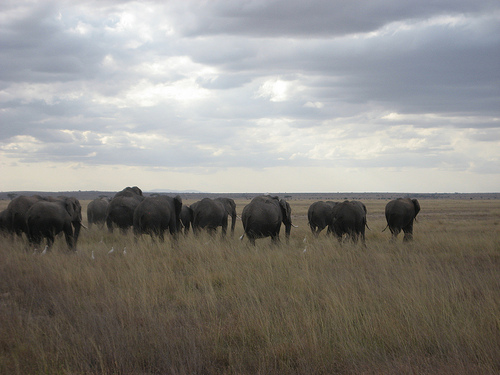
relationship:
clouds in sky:
[83, 47, 220, 136] [46, 8, 493, 144]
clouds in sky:
[316, 84, 389, 128] [93, 17, 444, 177]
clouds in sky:
[370, 81, 460, 141] [57, 8, 485, 178]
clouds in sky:
[95, 70, 149, 114] [74, 25, 483, 164]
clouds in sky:
[139, 49, 203, 92] [155, 51, 479, 190]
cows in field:
[16, 190, 425, 245] [0, 182, 483, 334]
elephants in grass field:
[11, 189, 431, 270] [31, 210, 485, 362]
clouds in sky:
[22, 28, 97, 125] [11, 32, 111, 89]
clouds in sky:
[330, 52, 416, 114] [38, 32, 468, 177]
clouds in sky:
[386, 13, 476, 78] [2, 2, 497, 191]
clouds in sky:
[3, 0, 496, 172] [2, 2, 497, 191]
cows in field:
[2, 186, 422, 248] [0, 192, 497, 370]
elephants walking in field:
[189, 197, 237, 238] [0, 192, 497, 370]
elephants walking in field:
[306, 200, 336, 237] [0, 192, 497, 370]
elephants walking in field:
[185, 195, 294, 242] [0, 192, 497, 370]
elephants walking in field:
[88, 184, 181, 240] [0, 192, 497, 370]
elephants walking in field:
[3, 194, 85, 249] [0, 192, 497, 370]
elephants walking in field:
[91, 184, 238, 236] [0, 192, 497, 370]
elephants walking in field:
[240, 192, 421, 245] [0, 192, 497, 370]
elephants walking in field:
[88, 186, 419, 239] [0, 192, 497, 370]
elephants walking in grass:
[189, 197, 237, 238] [0, 192, 497, 369]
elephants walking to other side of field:
[189, 197, 237, 238] [0, 192, 497, 370]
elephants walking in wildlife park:
[189, 197, 237, 238] [2, 190, 497, 371]